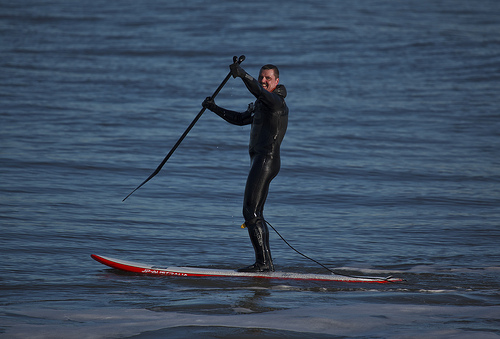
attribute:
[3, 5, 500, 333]
water — blue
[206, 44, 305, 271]
man — standing, wet, smiling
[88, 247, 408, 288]
board — red, white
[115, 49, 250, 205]
oar — black, pointed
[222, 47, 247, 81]
hand — gloved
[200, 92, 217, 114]
hand — gloved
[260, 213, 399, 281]
wire — black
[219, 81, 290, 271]
wetsuit — black, wet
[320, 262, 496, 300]
ripple — small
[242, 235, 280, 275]
booties — black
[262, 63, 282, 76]
hair — brown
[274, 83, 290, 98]
hood — black